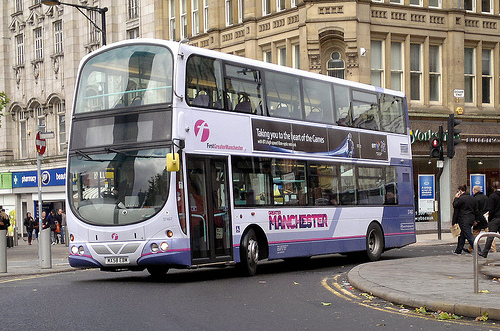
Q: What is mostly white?
A: Bus.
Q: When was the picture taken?
A: Daytime.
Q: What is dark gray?
A: Street.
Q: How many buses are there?
A: One.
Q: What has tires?
A: A bus.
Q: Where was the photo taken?
A: In the middle of the street.